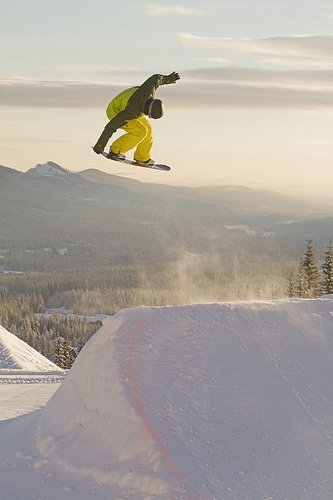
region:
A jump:
[54, 279, 331, 495]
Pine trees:
[257, 234, 331, 292]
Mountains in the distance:
[0, 157, 332, 254]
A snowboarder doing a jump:
[84, 58, 190, 186]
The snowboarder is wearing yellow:
[81, 48, 203, 198]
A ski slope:
[0, 317, 64, 370]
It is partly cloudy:
[179, 30, 331, 120]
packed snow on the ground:
[3, 384, 52, 412]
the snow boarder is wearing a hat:
[83, 50, 197, 182]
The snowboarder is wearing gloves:
[72, 38, 201, 183]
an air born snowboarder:
[81, 63, 205, 190]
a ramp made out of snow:
[25, 254, 331, 492]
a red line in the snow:
[109, 312, 194, 493]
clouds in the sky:
[207, 66, 314, 213]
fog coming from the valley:
[133, 219, 289, 300]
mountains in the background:
[2, 153, 108, 244]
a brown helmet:
[138, 94, 174, 121]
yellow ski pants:
[111, 114, 163, 163]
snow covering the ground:
[5, 387, 39, 414]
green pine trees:
[282, 228, 331, 302]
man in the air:
[95, 50, 207, 185]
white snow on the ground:
[198, 372, 266, 454]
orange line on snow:
[120, 308, 169, 479]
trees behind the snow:
[86, 237, 137, 307]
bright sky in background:
[210, 111, 288, 177]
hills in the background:
[14, 143, 73, 215]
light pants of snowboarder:
[115, 117, 158, 156]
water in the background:
[219, 213, 262, 259]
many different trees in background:
[28, 256, 111, 312]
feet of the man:
[105, 152, 178, 176]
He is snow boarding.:
[67, 67, 203, 188]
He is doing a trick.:
[84, 65, 187, 196]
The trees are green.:
[279, 223, 330, 300]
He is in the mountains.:
[21, 158, 329, 427]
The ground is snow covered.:
[119, 314, 326, 478]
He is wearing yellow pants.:
[91, 59, 189, 200]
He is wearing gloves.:
[78, 64, 189, 179]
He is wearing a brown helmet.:
[79, 61, 201, 188]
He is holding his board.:
[62, 55, 186, 183]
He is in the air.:
[54, 53, 322, 362]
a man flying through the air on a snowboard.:
[87, 58, 183, 179]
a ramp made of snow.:
[0, 300, 331, 499]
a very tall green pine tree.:
[299, 241, 323, 297]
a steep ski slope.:
[0, 323, 82, 386]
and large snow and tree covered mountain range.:
[0, 159, 331, 270]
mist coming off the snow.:
[121, 207, 287, 298]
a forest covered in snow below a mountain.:
[0, 254, 328, 305]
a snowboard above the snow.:
[94, 129, 195, 175]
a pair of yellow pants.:
[99, 112, 165, 167]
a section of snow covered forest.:
[73, 304, 110, 311]